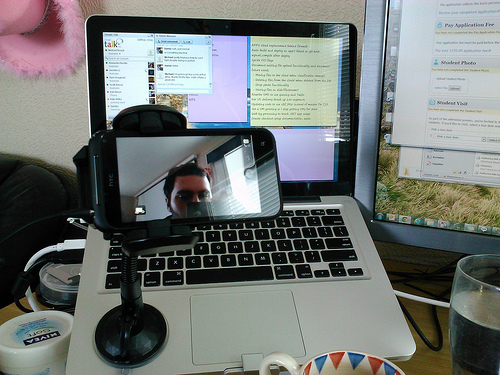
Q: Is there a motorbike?
A: No, there are no motorcycles.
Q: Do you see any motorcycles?
A: No, there are no motorcycles.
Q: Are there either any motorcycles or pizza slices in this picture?
A: No, there are no motorcycles or pizza slices.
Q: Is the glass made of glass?
A: Yes, the glass is made of glass.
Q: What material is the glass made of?
A: The glass is made of glass.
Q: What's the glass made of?
A: The glass is made of glass.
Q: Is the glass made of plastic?
A: No, the glass is made of glass.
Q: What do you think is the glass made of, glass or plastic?
A: The glass is made of glass.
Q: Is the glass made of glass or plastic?
A: The glass is made of glass.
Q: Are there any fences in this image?
A: No, there are no fences.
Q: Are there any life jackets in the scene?
A: No, there are no life jackets.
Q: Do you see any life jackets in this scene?
A: No, there are no life jackets.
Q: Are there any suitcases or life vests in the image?
A: No, there are no life vests or suitcases.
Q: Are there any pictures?
A: No, there are no pictures.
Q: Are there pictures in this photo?
A: No, there are no pictures.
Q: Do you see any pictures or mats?
A: No, there are no pictures or mats.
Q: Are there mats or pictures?
A: No, there are no pictures or mats.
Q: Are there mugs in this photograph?
A: Yes, there is a mug.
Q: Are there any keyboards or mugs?
A: Yes, there is a mug.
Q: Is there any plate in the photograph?
A: No, there are no plates.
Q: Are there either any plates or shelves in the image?
A: No, there are no plates or shelves.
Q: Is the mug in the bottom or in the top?
A: The mug is in the bottom of the image.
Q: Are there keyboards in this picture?
A: Yes, there is a keyboard.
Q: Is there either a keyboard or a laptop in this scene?
A: Yes, there is a keyboard.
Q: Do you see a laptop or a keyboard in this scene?
A: Yes, there is a keyboard.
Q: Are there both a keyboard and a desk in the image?
A: Yes, there are both a keyboard and a desk.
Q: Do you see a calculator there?
A: No, there are no calculators.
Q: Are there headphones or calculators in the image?
A: No, there are no calculators or headphones.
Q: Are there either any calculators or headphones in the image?
A: No, there are no calculators or headphones.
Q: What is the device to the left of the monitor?
A: The device is a keyboard.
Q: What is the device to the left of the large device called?
A: The device is a keyboard.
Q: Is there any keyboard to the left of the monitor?
A: Yes, there is a keyboard to the left of the monitor.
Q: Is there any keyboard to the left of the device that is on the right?
A: Yes, there is a keyboard to the left of the monitor.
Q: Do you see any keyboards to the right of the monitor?
A: No, the keyboard is to the left of the monitor.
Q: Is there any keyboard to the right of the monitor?
A: No, the keyboard is to the left of the monitor.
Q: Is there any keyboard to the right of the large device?
A: No, the keyboard is to the left of the monitor.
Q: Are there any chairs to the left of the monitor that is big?
A: No, there is a keyboard to the left of the monitor.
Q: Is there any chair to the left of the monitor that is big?
A: No, there is a keyboard to the left of the monitor.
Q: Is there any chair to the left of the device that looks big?
A: No, there is a keyboard to the left of the monitor.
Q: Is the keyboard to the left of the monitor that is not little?
A: Yes, the keyboard is to the left of the monitor.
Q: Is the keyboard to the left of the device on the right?
A: Yes, the keyboard is to the left of the monitor.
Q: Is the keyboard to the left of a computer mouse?
A: No, the keyboard is to the left of the monitor.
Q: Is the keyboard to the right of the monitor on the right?
A: No, the keyboard is to the left of the monitor.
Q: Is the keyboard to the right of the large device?
A: No, the keyboard is to the left of the monitor.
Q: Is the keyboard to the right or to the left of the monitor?
A: The keyboard is to the left of the monitor.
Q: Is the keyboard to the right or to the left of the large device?
A: The keyboard is to the left of the monitor.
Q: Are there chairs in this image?
A: No, there are no chairs.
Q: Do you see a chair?
A: No, there are no chairs.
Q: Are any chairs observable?
A: No, there are no chairs.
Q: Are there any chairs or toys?
A: No, there are no chairs or toys.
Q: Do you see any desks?
A: Yes, there is a desk.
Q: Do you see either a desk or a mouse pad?
A: Yes, there is a desk.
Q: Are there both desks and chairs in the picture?
A: No, there is a desk but no chairs.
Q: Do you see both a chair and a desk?
A: No, there is a desk but no chairs.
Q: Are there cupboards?
A: No, there are no cupboards.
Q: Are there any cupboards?
A: No, there are no cupboards.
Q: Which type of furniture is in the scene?
A: The furniture is a desk.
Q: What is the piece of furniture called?
A: The piece of furniture is a desk.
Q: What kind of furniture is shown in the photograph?
A: The furniture is a desk.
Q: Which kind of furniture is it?
A: The piece of furniture is a desk.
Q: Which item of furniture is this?
A: That is a desk.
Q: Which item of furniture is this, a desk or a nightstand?
A: That is a desk.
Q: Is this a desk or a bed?
A: This is a desk.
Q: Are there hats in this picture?
A: Yes, there is a hat.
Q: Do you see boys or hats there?
A: Yes, there is a hat.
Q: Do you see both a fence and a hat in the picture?
A: No, there is a hat but no fences.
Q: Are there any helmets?
A: No, there are no helmets.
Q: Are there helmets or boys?
A: No, there are no helmets or boys.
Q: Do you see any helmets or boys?
A: No, there are no helmets or boys.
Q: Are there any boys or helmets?
A: No, there are no helmets or boys.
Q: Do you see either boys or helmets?
A: No, there are no helmets or boys.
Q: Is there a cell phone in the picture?
A: Yes, there is a cell phone.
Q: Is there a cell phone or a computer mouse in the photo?
A: Yes, there is a cell phone.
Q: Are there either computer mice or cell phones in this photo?
A: Yes, there is a cell phone.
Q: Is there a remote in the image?
A: No, there are no remote controls.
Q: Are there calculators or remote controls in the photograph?
A: No, there are no remote controls or calculators.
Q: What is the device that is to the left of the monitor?
A: The device is a cell phone.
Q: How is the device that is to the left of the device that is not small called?
A: The device is a cell phone.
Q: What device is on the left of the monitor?
A: The device is a cell phone.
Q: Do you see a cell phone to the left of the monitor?
A: Yes, there is a cell phone to the left of the monitor.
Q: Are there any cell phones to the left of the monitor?
A: Yes, there is a cell phone to the left of the monitor.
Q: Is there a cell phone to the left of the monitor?
A: Yes, there is a cell phone to the left of the monitor.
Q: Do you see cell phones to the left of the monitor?
A: Yes, there is a cell phone to the left of the monitor.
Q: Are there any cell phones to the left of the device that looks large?
A: Yes, there is a cell phone to the left of the monitor.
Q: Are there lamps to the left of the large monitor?
A: No, there is a cell phone to the left of the monitor.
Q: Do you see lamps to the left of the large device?
A: No, there is a cell phone to the left of the monitor.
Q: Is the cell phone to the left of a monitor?
A: Yes, the cell phone is to the left of a monitor.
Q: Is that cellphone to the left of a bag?
A: No, the cellphone is to the left of a monitor.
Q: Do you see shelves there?
A: No, there are no shelves.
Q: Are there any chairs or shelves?
A: No, there are no shelves or chairs.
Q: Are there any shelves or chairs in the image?
A: No, there are no shelves or chairs.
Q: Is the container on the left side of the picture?
A: Yes, the container is on the left of the image.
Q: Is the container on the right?
A: No, the container is on the left of the image.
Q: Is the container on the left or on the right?
A: The container is on the left of the image.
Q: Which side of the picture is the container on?
A: The container is on the left of the image.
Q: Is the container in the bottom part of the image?
A: Yes, the container is in the bottom of the image.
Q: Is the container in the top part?
A: No, the container is in the bottom of the image.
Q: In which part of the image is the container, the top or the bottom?
A: The container is in the bottom of the image.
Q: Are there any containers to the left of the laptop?
A: Yes, there is a container to the left of the laptop.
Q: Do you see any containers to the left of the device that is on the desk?
A: Yes, there is a container to the left of the laptop.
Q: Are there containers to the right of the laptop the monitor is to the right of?
A: No, the container is to the left of the laptop computer.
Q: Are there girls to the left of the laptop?
A: No, there is a container to the left of the laptop.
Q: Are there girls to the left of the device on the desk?
A: No, there is a container to the left of the laptop.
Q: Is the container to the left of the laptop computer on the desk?
A: Yes, the container is to the left of the laptop.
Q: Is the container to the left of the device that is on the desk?
A: Yes, the container is to the left of the laptop.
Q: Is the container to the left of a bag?
A: No, the container is to the left of the laptop.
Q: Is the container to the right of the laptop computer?
A: No, the container is to the left of the laptop computer.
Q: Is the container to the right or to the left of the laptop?
A: The container is to the left of the laptop.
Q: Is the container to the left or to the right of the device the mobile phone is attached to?
A: The container is to the left of the laptop.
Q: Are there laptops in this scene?
A: Yes, there is a laptop.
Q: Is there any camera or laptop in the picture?
A: Yes, there is a laptop.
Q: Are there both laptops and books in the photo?
A: No, there is a laptop but no books.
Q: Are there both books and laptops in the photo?
A: No, there is a laptop but no books.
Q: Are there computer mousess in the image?
A: No, there are no computer mousess.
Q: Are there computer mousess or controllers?
A: No, there are no computer mousess or controllers.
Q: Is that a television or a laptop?
A: That is a laptop.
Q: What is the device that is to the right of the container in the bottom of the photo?
A: The device is a laptop.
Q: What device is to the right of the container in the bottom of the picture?
A: The device is a laptop.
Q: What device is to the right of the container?
A: The device is a laptop.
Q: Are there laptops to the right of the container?
A: Yes, there is a laptop to the right of the container.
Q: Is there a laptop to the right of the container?
A: Yes, there is a laptop to the right of the container.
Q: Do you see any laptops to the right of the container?
A: Yes, there is a laptop to the right of the container.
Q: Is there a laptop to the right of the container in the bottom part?
A: Yes, there is a laptop to the right of the container.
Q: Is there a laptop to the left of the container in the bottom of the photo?
A: No, the laptop is to the right of the container.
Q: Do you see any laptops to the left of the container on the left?
A: No, the laptop is to the right of the container.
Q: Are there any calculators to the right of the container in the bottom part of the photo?
A: No, there is a laptop to the right of the container.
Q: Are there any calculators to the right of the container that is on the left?
A: No, there is a laptop to the right of the container.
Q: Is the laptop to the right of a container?
A: Yes, the laptop is to the right of a container.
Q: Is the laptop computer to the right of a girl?
A: No, the laptop computer is to the right of a container.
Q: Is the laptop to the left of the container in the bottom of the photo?
A: No, the laptop is to the right of the container.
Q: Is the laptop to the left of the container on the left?
A: No, the laptop is to the right of the container.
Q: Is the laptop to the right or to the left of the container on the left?
A: The laptop is to the right of the container.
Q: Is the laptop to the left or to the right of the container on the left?
A: The laptop is to the right of the container.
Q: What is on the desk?
A: The laptop is on the desk.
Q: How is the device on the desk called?
A: The device is a laptop.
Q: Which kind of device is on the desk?
A: The device is a laptop.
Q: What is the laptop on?
A: The laptop is on the desk.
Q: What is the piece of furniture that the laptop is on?
A: The piece of furniture is a desk.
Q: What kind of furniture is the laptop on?
A: The laptop is on the desk.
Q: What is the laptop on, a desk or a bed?
A: The laptop is on a desk.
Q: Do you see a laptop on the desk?
A: Yes, there is a laptop on the desk.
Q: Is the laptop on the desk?
A: Yes, the laptop is on the desk.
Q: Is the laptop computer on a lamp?
A: No, the laptop computer is on the desk.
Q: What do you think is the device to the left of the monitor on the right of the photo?
A: The device is a laptop.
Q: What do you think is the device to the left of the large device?
A: The device is a laptop.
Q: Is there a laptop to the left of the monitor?
A: Yes, there is a laptop to the left of the monitor.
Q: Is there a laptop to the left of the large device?
A: Yes, there is a laptop to the left of the monitor.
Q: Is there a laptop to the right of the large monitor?
A: No, the laptop is to the left of the monitor.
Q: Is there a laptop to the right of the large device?
A: No, the laptop is to the left of the monitor.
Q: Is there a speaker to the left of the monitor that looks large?
A: No, there is a laptop to the left of the monitor.